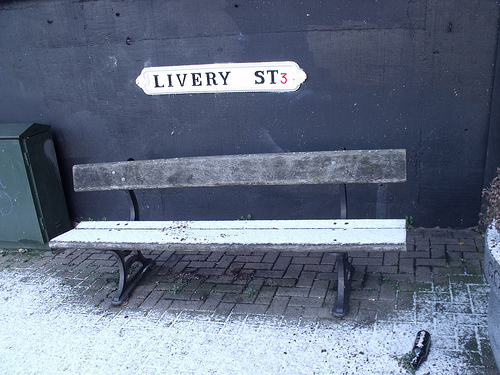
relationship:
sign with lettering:
[134, 59, 308, 97] [150, 68, 233, 90]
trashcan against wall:
[2, 119, 72, 244] [0, 2, 497, 240]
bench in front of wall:
[47, 144, 413, 317] [0, 2, 497, 240]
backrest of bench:
[66, 143, 413, 195] [47, 144, 413, 317]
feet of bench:
[106, 256, 357, 321] [47, 144, 413, 317]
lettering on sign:
[150, 68, 233, 90] [134, 59, 308, 97]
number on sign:
[278, 70, 290, 90] [134, 59, 308, 97]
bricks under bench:
[182, 258, 306, 322] [47, 144, 413, 317]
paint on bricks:
[108, 315, 275, 356] [2, 264, 388, 374]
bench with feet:
[47, 144, 413, 317] [106, 256, 357, 321]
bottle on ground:
[409, 328, 431, 370] [0, 232, 483, 373]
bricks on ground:
[182, 258, 306, 322] [0, 232, 483, 373]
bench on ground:
[47, 144, 413, 317] [0, 232, 483, 373]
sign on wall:
[134, 59, 308, 97] [0, 2, 497, 240]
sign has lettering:
[134, 59, 308, 97] [150, 68, 233, 90]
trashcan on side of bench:
[2, 119, 72, 244] [47, 144, 413, 317]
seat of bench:
[45, 218, 413, 252] [47, 144, 413, 317]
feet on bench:
[106, 256, 357, 321] [47, 144, 413, 317]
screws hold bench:
[331, 219, 351, 245] [47, 144, 413, 317]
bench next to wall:
[47, 144, 413, 317] [0, 2, 497, 240]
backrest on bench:
[66, 143, 413, 195] [47, 144, 413, 317]